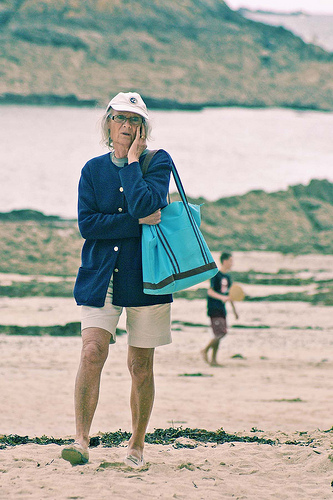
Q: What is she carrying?
A: Bag.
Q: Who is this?
A: Lady.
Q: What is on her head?
A: Hat.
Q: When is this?
A: Daytime.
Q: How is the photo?
A: Clear.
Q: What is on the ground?
A: Sand.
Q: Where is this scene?
A: At the beach.